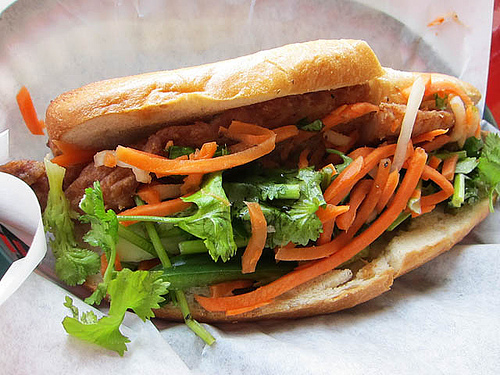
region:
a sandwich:
[106, 137, 223, 217]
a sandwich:
[191, 135, 344, 360]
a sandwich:
[193, 222, 306, 337]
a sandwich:
[170, 126, 287, 314]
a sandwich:
[241, 182, 391, 362]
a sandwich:
[151, 95, 267, 255]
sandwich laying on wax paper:
[15, 42, 495, 364]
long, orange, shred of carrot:
[113, 126, 277, 173]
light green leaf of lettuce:
[58, 267, 180, 352]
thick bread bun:
[31, 21, 358, 153]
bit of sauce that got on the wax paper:
[421, 8, 467, 44]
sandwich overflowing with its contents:
[39, 58, 491, 359]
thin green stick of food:
[141, 223, 237, 349]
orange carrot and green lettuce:
[282, 173, 367, 265]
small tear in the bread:
[378, 243, 412, 291]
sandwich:
[7, 34, 499, 349]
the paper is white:
[400, 270, 494, 364]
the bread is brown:
[107, 64, 345, 119]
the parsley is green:
[72, 194, 171, 371]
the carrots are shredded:
[335, 153, 437, 253]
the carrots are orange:
[332, 157, 446, 266]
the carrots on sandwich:
[332, 172, 482, 314]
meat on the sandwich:
[59, 140, 164, 208]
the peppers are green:
[139, 241, 279, 287]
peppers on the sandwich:
[147, 250, 288, 331]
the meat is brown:
[67, 142, 147, 214]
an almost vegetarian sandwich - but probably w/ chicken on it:
[1, 33, 498, 367]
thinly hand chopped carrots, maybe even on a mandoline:
[8, 82, 498, 334]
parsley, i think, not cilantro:
[43, 182, 188, 374]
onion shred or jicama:
[352, 71, 437, 193]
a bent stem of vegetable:
[177, 303, 222, 349]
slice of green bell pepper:
[127, 251, 302, 297]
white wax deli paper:
[0, 1, 498, 374]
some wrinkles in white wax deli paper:
[0, 258, 424, 374]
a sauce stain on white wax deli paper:
[415, 6, 472, 38]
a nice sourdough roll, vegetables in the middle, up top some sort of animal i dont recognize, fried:
[0, 35, 497, 328]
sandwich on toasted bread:
[57, 46, 369, 128]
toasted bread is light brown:
[60, 31, 400, 149]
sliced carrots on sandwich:
[134, 116, 374, 178]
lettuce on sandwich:
[99, 125, 270, 294]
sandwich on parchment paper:
[85, 68, 469, 303]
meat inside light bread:
[78, 86, 334, 221]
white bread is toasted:
[74, 58, 349, 99]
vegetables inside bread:
[148, 108, 395, 265]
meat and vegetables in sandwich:
[43, 137, 385, 296]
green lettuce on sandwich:
[139, 161, 361, 271]